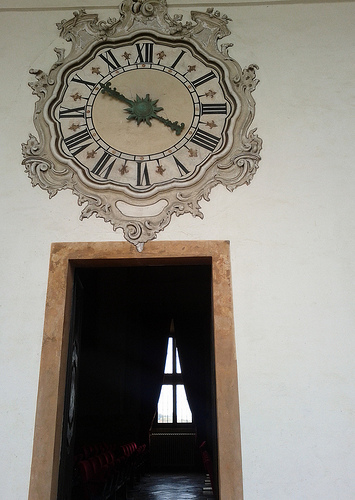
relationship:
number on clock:
[133, 41, 155, 69] [18, 0, 265, 253]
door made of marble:
[23, 239, 243, 499] [217, 240, 234, 482]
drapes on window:
[77, 271, 173, 444] [153, 338, 196, 429]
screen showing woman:
[58, 279, 94, 456] [68, 369, 77, 425]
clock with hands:
[18, 0, 265, 253] [99, 83, 185, 134]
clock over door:
[18, 0, 265, 253] [23, 239, 243, 499]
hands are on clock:
[99, 83, 185, 134] [18, 0, 265, 253]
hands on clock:
[99, 83, 185, 134] [18, 0, 265, 253]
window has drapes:
[153, 338, 196, 429] [77, 271, 173, 444]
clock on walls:
[18, 0, 265, 253] [2, 1, 349, 500]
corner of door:
[204, 238, 233, 265] [23, 239, 243, 499]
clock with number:
[18, 0, 265, 253] [133, 41, 155, 69]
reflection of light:
[154, 475, 200, 499] [153, 338, 196, 429]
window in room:
[153, 338, 196, 429] [64, 261, 217, 495]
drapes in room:
[77, 271, 173, 444] [64, 261, 217, 495]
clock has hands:
[18, 0, 265, 253] [99, 83, 185, 134]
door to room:
[23, 239, 243, 499] [64, 261, 217, 495]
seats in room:
[76, 440, 145, 492] [64, 261, 217, 495]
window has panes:
[153, 338, 196, 429] [156, 383, 174, 423]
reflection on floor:
[154, 475, 200, 499] [115, 450, 206, 497]